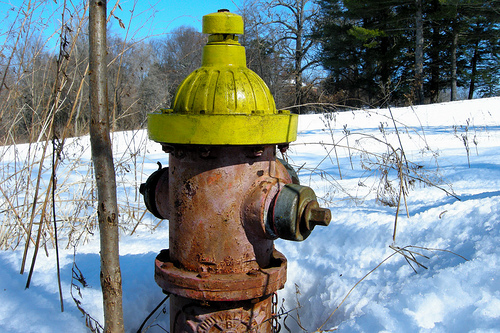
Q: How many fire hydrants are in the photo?
A: One.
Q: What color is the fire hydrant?
A: Green and brown.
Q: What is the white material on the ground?
A: Snow.